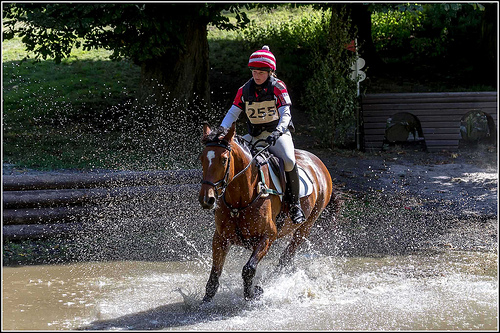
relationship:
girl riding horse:
[220, 46, 306, 222] [194, 124, 340, 305]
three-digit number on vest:
[248, 101, 280, 121] [238, 78, 279, 136]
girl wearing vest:
[220, 46, 306, 222] [238, 78, 279, 136]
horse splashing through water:
[194, 124, 340, 305] [0, 154, 499, 332]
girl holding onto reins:
[220, 46, 306, 222] [227, 142, 271, 181]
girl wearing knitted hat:
[220, 46, 306, 222] [238, 40, 279, 75]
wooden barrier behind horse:
[360, 89, 498, 152] [194, 124, 340, 305]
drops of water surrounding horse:
[142, 116, 176, 134] [194, 124, 340, 305]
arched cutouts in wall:
[384, 112, 422, 153] [352, 88, 483, 155]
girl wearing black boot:
[220, 46, 306, 222] [281, 157, 314, 225]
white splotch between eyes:
[204, 147, 218, 173] [192, 149, 233, 167]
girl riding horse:
[217, 39, 308, 231] [194, 124, 340, 305]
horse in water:
[194, 124, 340, 305] [5, 213, 474, 331]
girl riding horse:
[220, 46, 306, 222] [194, 121, 344, 312]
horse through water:
[194, 121, 344, 312] [4, 241, 481, 331]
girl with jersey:
[220, 46, 306, 222] [221, 72, 294, 137]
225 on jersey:
[244, 101, 278, 122] [221, 72, 294, 137]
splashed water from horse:
[269, 254, 345, 302] [194, 121, 344, 312]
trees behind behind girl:
[1, 0, 499, 141] [220, 46, 306, 222]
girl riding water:
[217, 39, 308, 231] [5, 227, 484, 331]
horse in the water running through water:
[187, 116, 337, 309] [4, 241, 481, 331]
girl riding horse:
[220, 46, 311, 237] [187, 111, 351, 317]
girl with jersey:
[220, 46, 311, 237] [217, 67, 299, 141]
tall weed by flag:
[323, 40, 356, 142] [333, 36, 360, 146]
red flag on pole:
[333, 31, 359, 62] [353, 39, 361, 130]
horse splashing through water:
[194, 124, 340, 305] [4, 241, 481, 331]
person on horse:
[212, 40, 303, 229] [186, 115, 339, 312]